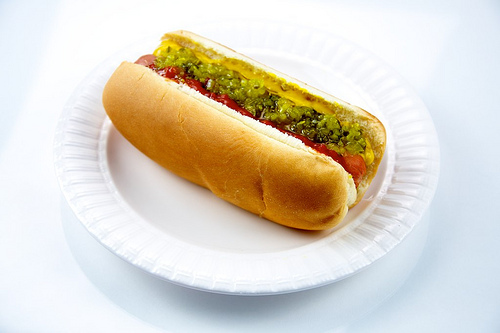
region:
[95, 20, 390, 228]
a hot dog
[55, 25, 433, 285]
a hot dog on a white plate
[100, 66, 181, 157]
a hot dog bun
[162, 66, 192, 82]
ketchup in a hot dog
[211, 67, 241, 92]
relish on a hot dog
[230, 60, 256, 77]
mustard on a hot dog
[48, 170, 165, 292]
a white plate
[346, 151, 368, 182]
a wiener in a hot dog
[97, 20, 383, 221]
a hot dog with mustard, ketchup and relish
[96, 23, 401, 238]
a hot dog with condiments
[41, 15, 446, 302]
a hotdog on a paper plate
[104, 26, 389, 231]
a hotdog in a bun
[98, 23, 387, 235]
a hotdog in a bun with condiments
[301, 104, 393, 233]
a hotdog with ketchup, mustard and relish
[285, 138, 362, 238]
a hotdog bun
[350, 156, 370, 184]
a hotdog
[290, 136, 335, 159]
a tomato ketchup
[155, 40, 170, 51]
a mustard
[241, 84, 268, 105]
a relish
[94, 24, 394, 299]
a ready to eat hotdog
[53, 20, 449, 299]
hot dog on white plate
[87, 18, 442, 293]
white plate with hot dog on it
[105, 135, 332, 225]
breaded hot dog bun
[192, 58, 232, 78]
green relish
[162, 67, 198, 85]
red ketchup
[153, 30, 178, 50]
yellow deli mustard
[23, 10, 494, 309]
white plate on table with hot dog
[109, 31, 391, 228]
hot dog with relish, mustard and ketchup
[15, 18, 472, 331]
white paper plate on white table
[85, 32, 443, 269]
one hot dog on plate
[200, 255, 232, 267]
white paper plate on top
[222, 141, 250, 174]
bun is laying on the plate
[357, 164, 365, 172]
hotdog is laying long in the bun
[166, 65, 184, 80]
red ketchup on the hotdog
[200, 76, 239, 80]
relish is laying on top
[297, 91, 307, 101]
mustard is on the bun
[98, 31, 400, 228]
delicious hotdog is on the plate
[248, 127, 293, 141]
inside the bun is white bread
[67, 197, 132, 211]
line going around the edge of the plate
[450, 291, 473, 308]
table is white that holding the plate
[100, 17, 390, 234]
A hotdog with relish, ketchup, and mustard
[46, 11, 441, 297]
A white paper plate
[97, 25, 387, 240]
A brown hotdog bun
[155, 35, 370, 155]
Green sweet relish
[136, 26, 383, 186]
Mustard, ketchup, and relish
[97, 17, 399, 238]
A hotdog in a hotdog bun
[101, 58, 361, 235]
A piece of a hotdog bun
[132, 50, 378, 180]
A beef hotdog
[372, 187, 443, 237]
Ridges on a paper plate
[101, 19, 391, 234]
White bread hotdog bun